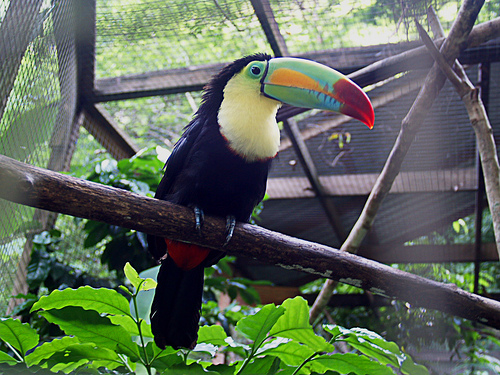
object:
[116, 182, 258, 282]
rear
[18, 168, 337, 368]
tree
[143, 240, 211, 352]
tail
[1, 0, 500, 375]
cage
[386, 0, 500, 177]
branch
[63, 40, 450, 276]
fencing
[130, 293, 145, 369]
stem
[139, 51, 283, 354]
feathers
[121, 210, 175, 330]
tips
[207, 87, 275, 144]
neck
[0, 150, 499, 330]
stick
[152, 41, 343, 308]
bird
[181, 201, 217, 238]
feet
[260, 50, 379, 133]
beak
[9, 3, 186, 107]
enclosure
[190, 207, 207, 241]
claw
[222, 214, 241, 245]
claw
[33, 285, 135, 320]
leaf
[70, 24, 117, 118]
beam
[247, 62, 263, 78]
eye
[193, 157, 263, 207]
plummage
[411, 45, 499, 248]
stick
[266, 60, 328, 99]
streak